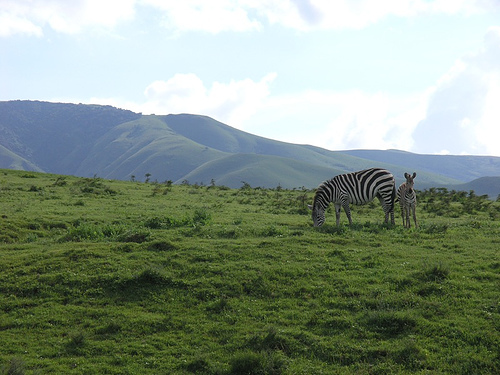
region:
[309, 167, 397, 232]
a black and white zebra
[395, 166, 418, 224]
a black and white baby zebra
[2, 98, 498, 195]
a rolling green mountain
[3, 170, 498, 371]
a grassy green field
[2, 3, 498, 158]
an overcast sky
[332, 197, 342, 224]
the leg of a zebra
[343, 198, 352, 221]
the leg of a zebra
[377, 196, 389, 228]
the leg of a zebra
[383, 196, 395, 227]
the leg of a zebra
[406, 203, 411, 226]
the leg of a zebra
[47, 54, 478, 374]
zebras on grass field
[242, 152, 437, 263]
two zebras standing by each other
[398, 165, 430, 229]
one zebra looking straight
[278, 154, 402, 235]
zebra with its head down in grass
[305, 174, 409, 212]
zebra grazing on food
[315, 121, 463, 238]
black and white stripes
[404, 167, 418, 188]
pointy ears of zebra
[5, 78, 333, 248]
mountain range in background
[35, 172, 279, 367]
green grassy field on ground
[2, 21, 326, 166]
clouds and mountains touching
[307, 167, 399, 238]
zebra grazing on grass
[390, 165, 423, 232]
young zebra staring at photographer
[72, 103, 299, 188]
rolling green mountains in background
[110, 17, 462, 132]
white puffy clouds in blue sky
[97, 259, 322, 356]
plush green grass in field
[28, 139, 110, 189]
valley in between mountains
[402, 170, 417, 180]
ears of zebra standing straight up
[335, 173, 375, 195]
black and white stripes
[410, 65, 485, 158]
large black storm cloud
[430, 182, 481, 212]
dark green bushes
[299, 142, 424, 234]
two zebras are grazing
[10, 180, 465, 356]
ground is green and grassy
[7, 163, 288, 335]
tufts of heavy grass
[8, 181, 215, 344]
thick and grassy land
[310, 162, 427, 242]
mother and young zebra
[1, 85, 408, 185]
large hills in background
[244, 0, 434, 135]
sky is blue and cloudy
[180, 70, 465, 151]
clouds are white and puffy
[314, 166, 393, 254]
zebra is bending over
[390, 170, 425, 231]
zebra is standing up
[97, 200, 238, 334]
nice pastured green grass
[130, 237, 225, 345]
nice pastured green grass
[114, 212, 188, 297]
nice pastured green grass